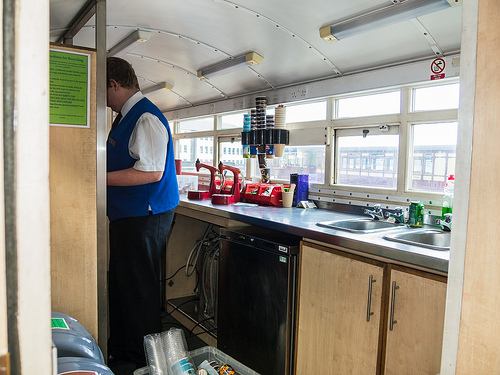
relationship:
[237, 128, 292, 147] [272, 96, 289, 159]
cup dispenser holding cups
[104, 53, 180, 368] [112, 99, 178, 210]
man in vest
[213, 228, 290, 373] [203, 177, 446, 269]
refrigerator under counter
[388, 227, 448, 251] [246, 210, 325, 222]
sink on counter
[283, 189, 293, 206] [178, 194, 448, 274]
cup on counter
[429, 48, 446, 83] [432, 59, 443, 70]
white sign with drawing